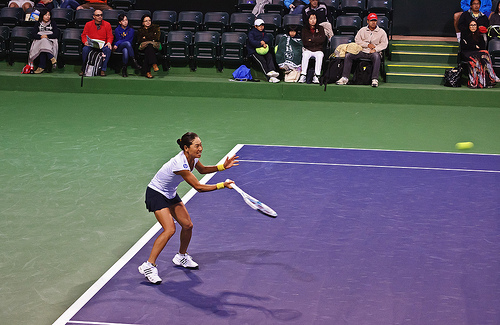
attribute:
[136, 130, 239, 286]
player — smiling, woman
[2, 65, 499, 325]
court — purple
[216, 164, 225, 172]
bands — yellow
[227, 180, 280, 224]
racket — white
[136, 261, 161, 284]
shoes — white, black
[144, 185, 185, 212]
skirt — black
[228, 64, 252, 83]
bag — blue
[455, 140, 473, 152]
ball — green, airborn, yellow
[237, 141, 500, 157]
lines — white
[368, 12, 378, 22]
cap — red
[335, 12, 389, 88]
person — sitting, watching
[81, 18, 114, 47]
sweater — red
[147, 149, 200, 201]
jersey — white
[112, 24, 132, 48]
shirt — blue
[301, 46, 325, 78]
pants — white